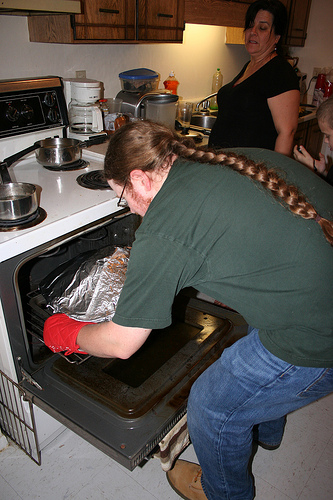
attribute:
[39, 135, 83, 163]
pot — silver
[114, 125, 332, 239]
man's hair — braided, red, brown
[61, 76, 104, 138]
coffee maker — white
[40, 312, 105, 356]
oven mitt — red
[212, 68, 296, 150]
woman's shirt — black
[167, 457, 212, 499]
boots — brown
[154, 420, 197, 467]
towel — brown, white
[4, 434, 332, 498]
floor — white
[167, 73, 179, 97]
dish soap — orange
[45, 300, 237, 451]
oven door — black